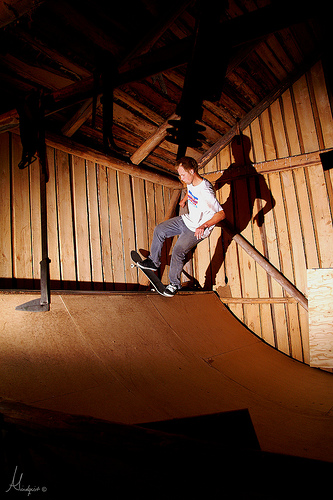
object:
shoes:
[134, 255, 158, 272]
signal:
[109, 80, 179, 121]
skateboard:
[129, 249, 165, 296]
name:
[0, 463, 49, 497]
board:
[305, 267, 332, 369]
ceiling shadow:
[138, 133, 276, 291]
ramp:
[0, 287, 332, 499]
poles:
[221, 220, 308, 316]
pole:
[30, 151, 51, 306]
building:
[0, 0, 332, 498]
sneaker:
[162, 280, 181, 298]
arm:
[203, 191, 226, 229]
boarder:
[137, 155, 226, 297]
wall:
[0, 128, 184, 290]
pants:
[147, 214, 203, 291]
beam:
[0, 0, 298, 135]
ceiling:
[0, 0, 332, 182]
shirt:
[180, 176, 224, 241]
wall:
[197, 49, 332, 374]